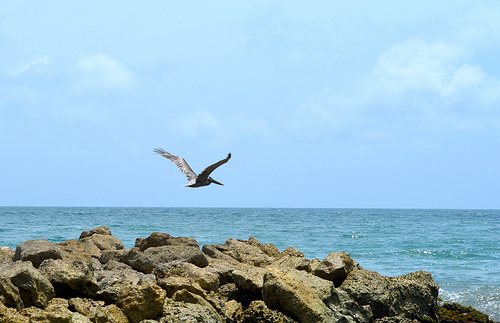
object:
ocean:
[1, 206, 499, 323]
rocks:
[260, 267, 334, 323]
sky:
[1, 2, 500, 207]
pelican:
[152, 145, 233, 188]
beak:
[211, 177, 224, 187]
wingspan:
[150, 145, 199, 179]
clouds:
[290, 36, 499, 138]